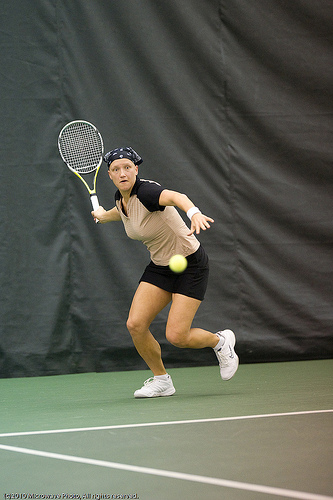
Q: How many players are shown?
A: One.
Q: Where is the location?
A: Tennis court.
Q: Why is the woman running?
A: To hit the ball.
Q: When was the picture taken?
A: Daytime.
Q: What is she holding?
A: A tennis racket.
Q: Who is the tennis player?
A: A woman.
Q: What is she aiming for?
A: A tennis ball.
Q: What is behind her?
A: A black curtain.